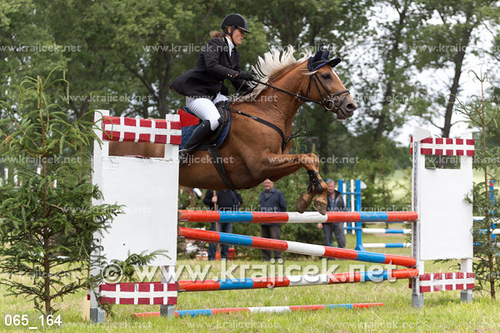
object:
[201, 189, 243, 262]
people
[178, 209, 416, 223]
bar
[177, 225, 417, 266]
bar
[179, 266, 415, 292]
bar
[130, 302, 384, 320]
bar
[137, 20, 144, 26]
leaves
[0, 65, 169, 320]
tree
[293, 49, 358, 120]
head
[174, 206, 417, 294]
obstacle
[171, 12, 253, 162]
jockey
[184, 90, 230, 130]
pants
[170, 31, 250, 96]
jacket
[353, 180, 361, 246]
post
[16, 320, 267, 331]
ground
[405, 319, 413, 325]
green grass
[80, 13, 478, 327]
hurdles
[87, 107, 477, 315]
barrier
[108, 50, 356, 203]
horse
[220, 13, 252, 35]
hat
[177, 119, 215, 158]
boots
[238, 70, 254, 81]
gloves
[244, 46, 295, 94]
mane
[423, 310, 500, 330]
ground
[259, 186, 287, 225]
jacket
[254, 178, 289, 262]
man